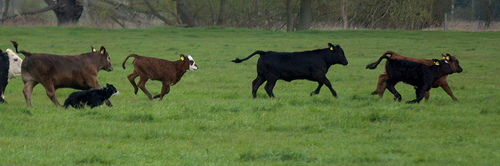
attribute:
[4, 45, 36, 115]
cow — white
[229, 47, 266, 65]
tail — UP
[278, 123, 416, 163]
grass — short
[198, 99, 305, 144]
grass — green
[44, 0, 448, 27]
trunks — dark, brown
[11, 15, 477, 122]
animals — running